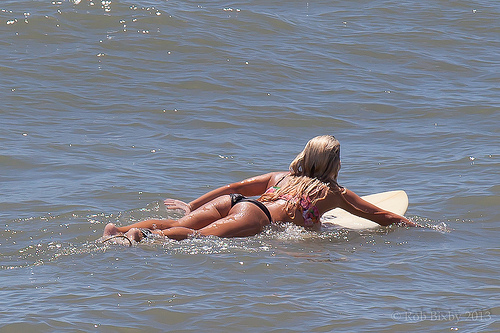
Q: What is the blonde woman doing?
A: Surfing.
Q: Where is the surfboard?
A: Below the woman.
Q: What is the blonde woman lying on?
A: The surfboard.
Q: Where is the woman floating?
A: On the water.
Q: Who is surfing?
A: The woman.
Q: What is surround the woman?
A: Water.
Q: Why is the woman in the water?
A: Surfing.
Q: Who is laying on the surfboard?
A: The woman.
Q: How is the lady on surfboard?
A: Lying down.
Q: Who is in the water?
A: A lady.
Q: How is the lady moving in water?
A: Floating.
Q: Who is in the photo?
A: A surfer.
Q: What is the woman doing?
A: Surfing.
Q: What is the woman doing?
A: On a surfboard.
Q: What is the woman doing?
A: Lying down.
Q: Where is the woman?
A: On the water.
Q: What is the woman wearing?
A: A bikini.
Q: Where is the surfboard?
A: White.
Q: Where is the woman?
A: On the water.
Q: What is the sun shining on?
A: The water.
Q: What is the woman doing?
A: On a surfboard.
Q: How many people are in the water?
A: One.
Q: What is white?
A: Surfboard.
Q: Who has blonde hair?
A: Surfer.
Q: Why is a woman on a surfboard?
A: To surf.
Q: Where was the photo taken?
A: In the ocean.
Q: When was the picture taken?
A: Daytime.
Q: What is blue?
A: Water.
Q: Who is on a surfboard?
A: A woman.